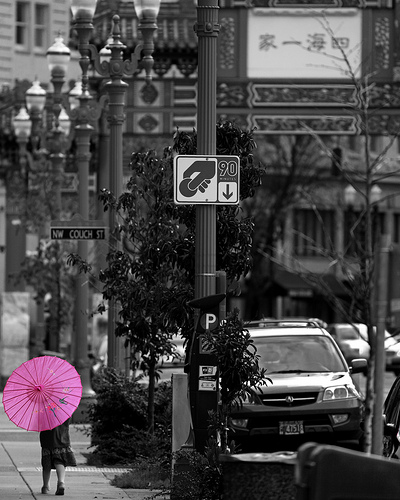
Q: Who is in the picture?
A: A woman.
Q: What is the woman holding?
A: An umbrella.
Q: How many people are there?
A: One.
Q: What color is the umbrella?
A: Pink.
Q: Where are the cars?
A: In the street.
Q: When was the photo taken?
A: During the day.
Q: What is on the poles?
A: Signs.